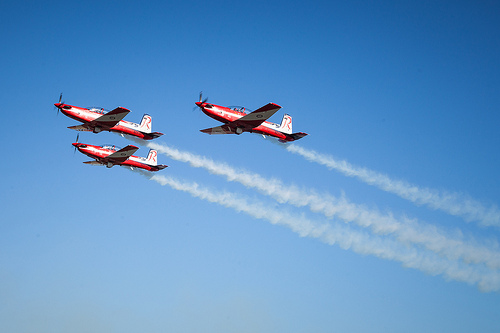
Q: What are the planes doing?
A: Flying.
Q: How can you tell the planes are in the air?
A: The ground can't be seen.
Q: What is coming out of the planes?
A: White smoke.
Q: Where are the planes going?
A: To the left.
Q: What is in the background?
A: A blue sky.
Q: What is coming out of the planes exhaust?
A: White smoke.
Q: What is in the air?
A: Planes.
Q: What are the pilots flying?
A: Planes.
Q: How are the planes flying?
A: In a formation.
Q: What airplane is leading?
A: The middle one.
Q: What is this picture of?
A: Three planes in sky.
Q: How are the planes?
A: Three identical red colored planes.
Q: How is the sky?
A: Blue and clear.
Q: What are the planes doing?
A: Flying in blue sky in a formation and ejecting smoke trails behind.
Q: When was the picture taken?
A: Daytime.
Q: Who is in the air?
A: 3 planes.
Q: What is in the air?
A: Planes.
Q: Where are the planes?
A: The sky.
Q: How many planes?
A: 3.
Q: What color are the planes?
A: Red.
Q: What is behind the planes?
A: Smoke.